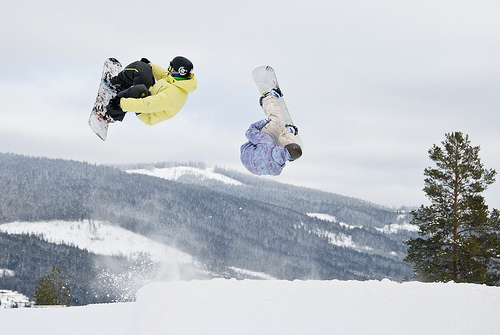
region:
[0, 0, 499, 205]
cloud cover in sky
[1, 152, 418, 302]
hill covered in trees and snow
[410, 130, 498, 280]
needles on pine tree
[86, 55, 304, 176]
two crouched airborne snowboarders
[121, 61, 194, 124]
yellow jacket with hood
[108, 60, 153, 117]
black pants on legs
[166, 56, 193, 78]
black helmet on head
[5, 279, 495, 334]
snowy surface of foreground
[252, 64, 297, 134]
top of flying snowboard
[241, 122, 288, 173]
back of purple jacket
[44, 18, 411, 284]
the men are snowboarding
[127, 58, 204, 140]
man's jacket is yellow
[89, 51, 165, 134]
man's pants are black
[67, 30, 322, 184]
the men are upside down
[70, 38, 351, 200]
the men are in the air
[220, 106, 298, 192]
man's jacket is blue and purple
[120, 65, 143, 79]
colored stripe on man's pants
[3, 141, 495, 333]
mountains in the background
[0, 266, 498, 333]
snow covering the ground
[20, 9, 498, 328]
men are above a hill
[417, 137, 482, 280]
tree behind the people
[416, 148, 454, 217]
leaves on the tree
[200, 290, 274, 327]
snow on the ground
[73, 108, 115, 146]
front of the board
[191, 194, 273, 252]
trees in the distance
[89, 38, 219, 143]
person wearing yellow outfit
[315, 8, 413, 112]
sky above the ground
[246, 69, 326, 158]
board under the person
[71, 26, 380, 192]
two people in the air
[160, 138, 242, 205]
hill in the background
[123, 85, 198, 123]
a yellow sweat shirt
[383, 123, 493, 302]
a big pine tree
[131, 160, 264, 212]
snow on a hill in back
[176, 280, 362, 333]
snow on the ground below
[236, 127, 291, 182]
a blue jacket on a person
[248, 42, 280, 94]
a snow covered board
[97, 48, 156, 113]
a person wearing black pants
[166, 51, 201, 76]
a black helmet on a head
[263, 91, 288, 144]
a white pair of snow pants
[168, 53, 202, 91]
Person wearing black helmet.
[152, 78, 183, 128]
Person wearing yellow coat.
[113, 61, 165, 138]
Person wearing black pants.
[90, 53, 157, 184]
Person doing trick on snowboard.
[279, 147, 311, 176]
Person wearing dark helmet.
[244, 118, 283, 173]
Person wearing blue and purple coat.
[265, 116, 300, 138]
Person wearing white pants.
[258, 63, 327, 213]
Person doing trick on snowboard.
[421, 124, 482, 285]
Large tree on mountain side.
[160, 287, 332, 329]
Ground is covered in snow.